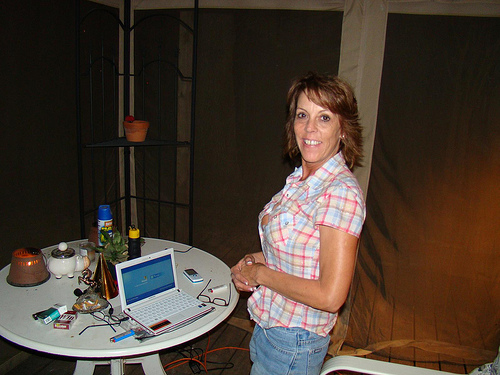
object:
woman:
[228, 72, 369, 374]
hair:
[281, 70, 368, 173]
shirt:
[246, 153, 369, 340]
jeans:
[248, 317, 333, 375]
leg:
[142, 356, 166, 373]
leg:
[109, 358, 128, 374]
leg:
[69, 359, 91, 374]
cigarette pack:
[53, 307, 80, 331]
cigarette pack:
[36, 301, 68, 325]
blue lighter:
[109, 327, 139, 344]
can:
[97, 205, 115, 246]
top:
[99, 205, 115, 220]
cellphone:
[183, 268, 205, 284]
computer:
[112, 248, 213, 333]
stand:
[75, 1, 213, 245]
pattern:
[295, 232, 312, 246]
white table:
[1, 232, 237, 374]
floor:
[95, 326, 251, 374]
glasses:
[195, 277, 235, 306]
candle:
[56, 241, 71, 253]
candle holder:
[6, 245, 52, 291]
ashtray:
[68, 291, 110, 311]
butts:
[80, 301, 92, 307]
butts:
[93, 297, 100, 307]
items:
[95, 226, 128, 267]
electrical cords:
[165, 344, 254, 374]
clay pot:
[121, 114, 151, 144]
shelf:
[74, 135, 191, 152]